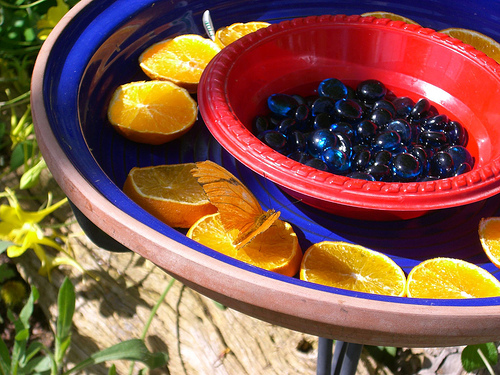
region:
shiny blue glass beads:
[250, 76, 468, 183]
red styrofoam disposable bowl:
[196, 13, 498, 222]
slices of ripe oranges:
[105, 7, 496, 294]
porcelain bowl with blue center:
[30, 0, 497, 345]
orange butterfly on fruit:
[185, 157, 300, 277]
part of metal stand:
[315, 331, 363, 372]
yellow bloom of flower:
[0, 183, 82, 274]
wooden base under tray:
[0, 155, 477, 371]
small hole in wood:
[290, 335, 315, 355]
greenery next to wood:
[0, 1, 176, 374]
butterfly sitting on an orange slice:
[196, 160, 281, 247]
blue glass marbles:
[293, 90, 398, 174]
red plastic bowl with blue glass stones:
[217, 25, 497, 200]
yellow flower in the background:
[0, 198, 80, 264]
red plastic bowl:
[245, 35, 380, 70]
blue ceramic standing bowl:
[76, 15, 104, 167]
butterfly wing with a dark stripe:
[197, 163, 251, 225]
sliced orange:
[116, 83, 193, 138]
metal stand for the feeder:
[318, 335, 360, 372]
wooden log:
[190, 325, 277, 368]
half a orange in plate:
[103, 81, 202, 141]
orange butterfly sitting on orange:
[194, 157, 290, 252]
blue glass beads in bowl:
[242, 48, 488, 179]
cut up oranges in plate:
[75, 20, 499, 317]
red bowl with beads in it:
[200, 0, 498, 242]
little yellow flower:
[1, 178, 70, 288]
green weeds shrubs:
[0, 273, 150, 373]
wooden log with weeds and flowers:
[4, 191, 404, 373]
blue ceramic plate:
[40, 7, 499, 351]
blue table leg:
[300, 328, 369, 373]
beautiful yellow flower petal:
[3, 196, 65, 258]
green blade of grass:
[43, 283, 93, 372]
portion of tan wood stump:
[112, 299, 248, 368]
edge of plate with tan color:
[29, 61, 58, 156]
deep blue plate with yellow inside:
[65, 117, 117, 179]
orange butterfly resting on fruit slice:
[198, 158, 280, 250]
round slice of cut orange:
[313, 239, 400, 301]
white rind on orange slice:
[320, 237, 356, 246]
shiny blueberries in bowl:
[338, 114, 425, 159]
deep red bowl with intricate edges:
[205, 21, 497, 231]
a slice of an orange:
[96, 74, 204, 133]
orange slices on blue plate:
[63, 7, 193, 274]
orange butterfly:
[192, 155, 307, 267]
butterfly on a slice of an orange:
[188, 163, 292, 279]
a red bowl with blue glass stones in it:
[227, 7, 497, 214]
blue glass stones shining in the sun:
[272, 65, 360, 172]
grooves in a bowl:
[98, 129, 208, 168]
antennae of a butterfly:
[258, 175, 303, 214]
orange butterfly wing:
[188, 157, 261, 219]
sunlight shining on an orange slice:
[132, 25, 230, 81]